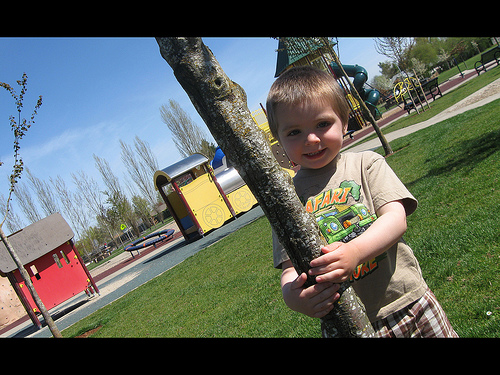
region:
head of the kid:
[223, 74, 375, 186]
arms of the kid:
[271, 198, 423, 308]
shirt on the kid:
[293, 151, 398, 271]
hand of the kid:
[298, 241, 360, 298]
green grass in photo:
[156, 259, 255, 324]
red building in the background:
[8, 187, 100, 302]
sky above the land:
[38, 115, 123, 157]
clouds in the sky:
[48, 118, 120, 182]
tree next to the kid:
[145, 43, 332, 275]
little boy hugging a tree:
[257, 64, 447, 349]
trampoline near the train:
[117, 221, 178, 263]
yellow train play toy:
[147, 162, 239, 234]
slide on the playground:
[344, 53, 391, 119]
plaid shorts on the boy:
[382, 285, 460, 336]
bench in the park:
[467, 43, 498, 86]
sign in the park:
[117, 218, 129, 235]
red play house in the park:
[6, 222, 102, 322]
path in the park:
[420, 110, 454, 135]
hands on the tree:
[287, 246, 352, 320]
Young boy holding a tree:
[248, 72, 444, 341]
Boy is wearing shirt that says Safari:
[293, 175, 398, 301]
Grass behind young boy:
[43, 97, 498, 337]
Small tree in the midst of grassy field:
[2, 74, 73, 336]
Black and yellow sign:
[115, 217, 127, 239]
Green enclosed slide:
[319, 57, 394, 126]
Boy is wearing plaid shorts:
[312, 304, 470, 337]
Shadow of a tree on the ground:
[386, 117, 498, 179]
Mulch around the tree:
[55, 319, 106, 346]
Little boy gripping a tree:
[257, 70, 461, 339]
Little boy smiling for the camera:
[262, 63, 459, 338]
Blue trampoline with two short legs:
[122, 227, 179, 257]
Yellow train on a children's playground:
[154, 145, 260, 237]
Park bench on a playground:
[472, 42, 499, 79]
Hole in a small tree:
[211, 72, 227, 92]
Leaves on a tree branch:
[1, 68, 47, 227]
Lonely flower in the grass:
[483, 304, 496, 321]